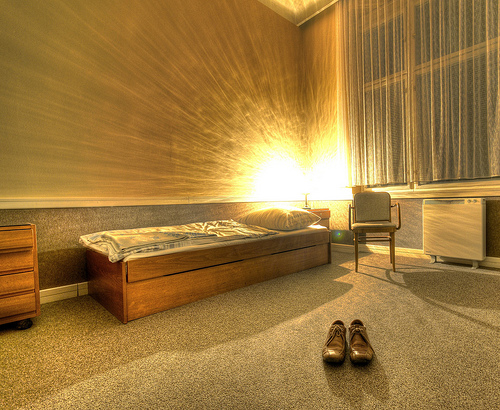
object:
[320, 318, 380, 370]
shoes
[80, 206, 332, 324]
bed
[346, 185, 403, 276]
chair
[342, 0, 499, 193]
window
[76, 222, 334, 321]
frame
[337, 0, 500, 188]
drapes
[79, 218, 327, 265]
covers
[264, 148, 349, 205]
light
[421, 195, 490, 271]
unit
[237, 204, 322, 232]
pillow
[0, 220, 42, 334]
dresser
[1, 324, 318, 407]
carpet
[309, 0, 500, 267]
wall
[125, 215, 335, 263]
drawer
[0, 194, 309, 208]
rail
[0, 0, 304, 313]
wall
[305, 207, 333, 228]
nightstand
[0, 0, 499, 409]
room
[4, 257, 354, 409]
shadow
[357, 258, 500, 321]
shadow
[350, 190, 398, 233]
seat